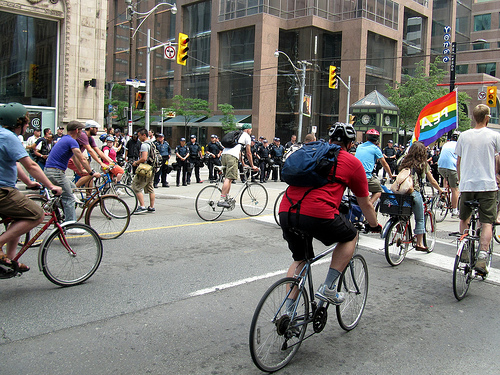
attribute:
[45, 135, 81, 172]
tee shirt — blue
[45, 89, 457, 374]
road — grey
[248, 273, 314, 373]
wheel — rear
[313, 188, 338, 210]
shirt — red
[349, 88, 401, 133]
tower — green, small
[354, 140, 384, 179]
shirt — turqoise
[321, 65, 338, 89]
stop light — yellow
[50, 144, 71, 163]
shirt — blue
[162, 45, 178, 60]
sign — red, white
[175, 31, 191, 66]
traffic light — yellow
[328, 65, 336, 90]
traffic light — yellow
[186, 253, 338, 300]
paint — white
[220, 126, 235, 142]
pack — black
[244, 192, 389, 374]
bike — silver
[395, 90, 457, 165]
flag — colorful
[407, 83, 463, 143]
flag — rainbow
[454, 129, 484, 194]
shirt — white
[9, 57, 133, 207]
building — tall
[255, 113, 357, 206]
pack — blue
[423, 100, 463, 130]
text — white